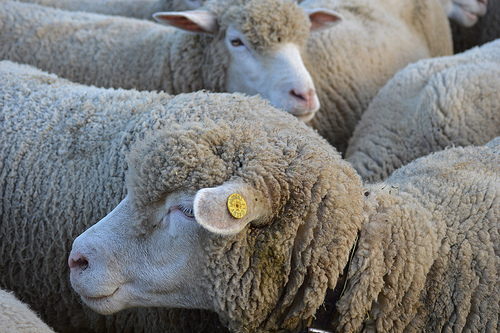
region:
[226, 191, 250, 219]
yellow tag in ear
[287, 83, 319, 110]
lamb has pink nose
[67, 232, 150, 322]
looks like lamb is smiling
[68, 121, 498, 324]
lamb with tan cream colored fur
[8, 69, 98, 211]
lamb has curly fur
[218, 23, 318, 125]
white face with small eyes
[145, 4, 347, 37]
two ears sticking straight out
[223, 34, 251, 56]
small black almond shape eyes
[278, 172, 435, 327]
neck of lamb has folds and wrinkles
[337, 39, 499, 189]
lamb is eating grass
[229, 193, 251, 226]
a tag in a sheep's ear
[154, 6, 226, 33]
the ear of a sheep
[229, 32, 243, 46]
the eye of a sheep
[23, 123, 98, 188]
grey wool on a sheep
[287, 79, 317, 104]
a sheep's nose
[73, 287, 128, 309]
the mouth of a sheep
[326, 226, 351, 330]
a black leather collar on a sheep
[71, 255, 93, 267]
a sheep's nostril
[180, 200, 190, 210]
a sheep's eyelash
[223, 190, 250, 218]
a gold tag with imprinted writing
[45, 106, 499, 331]
White sheep with yellow tag in ear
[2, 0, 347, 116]
Medium sized white sheep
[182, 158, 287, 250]
White sheep ear with yellow tag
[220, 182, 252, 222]
yellow plastic tag with writing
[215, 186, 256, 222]
Small yellow plastic tag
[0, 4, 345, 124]
White sheep standing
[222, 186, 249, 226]
Plastic tag colored yellow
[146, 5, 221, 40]
Medium sized white sheep ear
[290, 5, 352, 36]
White sheep ear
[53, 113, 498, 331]
White sheep standing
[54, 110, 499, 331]
This is a sheep.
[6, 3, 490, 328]
This is a group of sheep.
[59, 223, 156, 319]
This is a sheeps mouth.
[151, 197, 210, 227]
This is a sheep's eye.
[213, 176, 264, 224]
This is an ear tag.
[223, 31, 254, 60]
This is the sheep's right eye.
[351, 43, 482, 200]
This is a sheep's shoulders.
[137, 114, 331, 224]
This is a sheep's forehead.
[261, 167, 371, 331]
This is a sheep's neck.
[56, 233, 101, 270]
This is a sheep's nose.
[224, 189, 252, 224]
A gold disc on the sheep's ear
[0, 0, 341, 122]
A sheep staring at the camera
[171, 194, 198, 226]
Sheep's eye closed with eyelashes showing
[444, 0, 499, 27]
The mouth of a sheep in the upper right corner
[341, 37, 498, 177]
The back of a sheep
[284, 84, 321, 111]
The sheep's nose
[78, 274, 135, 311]
The sheep's mouth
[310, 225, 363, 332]
A black collar around the sheep's neck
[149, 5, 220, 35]
A sheep's ear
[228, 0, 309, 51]
Fur on top of the sheep's head